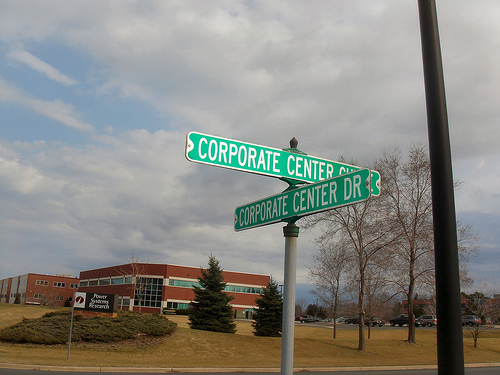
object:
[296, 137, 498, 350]
forest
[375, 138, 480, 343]
trees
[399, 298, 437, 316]
building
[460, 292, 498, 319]
building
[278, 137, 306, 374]
pole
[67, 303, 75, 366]
pole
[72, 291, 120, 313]
sign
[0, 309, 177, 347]
bushes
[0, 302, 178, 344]
grass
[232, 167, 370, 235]
text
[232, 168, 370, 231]
street sign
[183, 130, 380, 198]
street sign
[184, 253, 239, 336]
tree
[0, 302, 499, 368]
ground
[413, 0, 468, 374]
pole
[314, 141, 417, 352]
trees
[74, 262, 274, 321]
brick building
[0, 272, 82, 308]
brick building